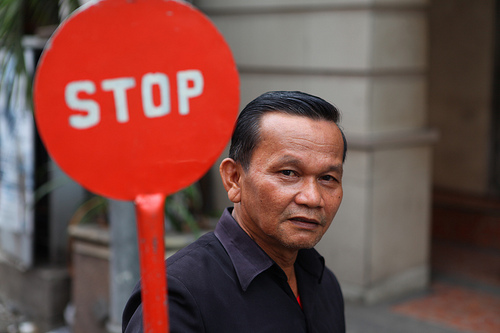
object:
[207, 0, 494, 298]
wall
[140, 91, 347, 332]
man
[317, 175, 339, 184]
eye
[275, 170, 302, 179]
eye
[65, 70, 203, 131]
word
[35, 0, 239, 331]
sign